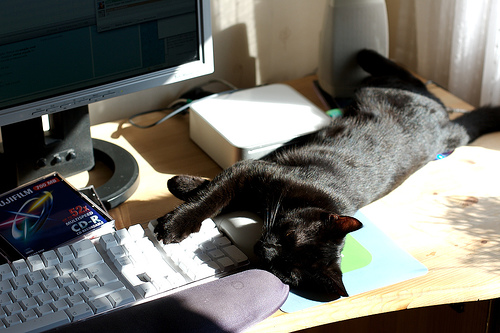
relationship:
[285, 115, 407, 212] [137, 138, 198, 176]
cat on table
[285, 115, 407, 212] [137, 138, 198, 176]
cat lying on table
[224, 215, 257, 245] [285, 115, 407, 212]
mouse under cat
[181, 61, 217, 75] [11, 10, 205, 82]
sunlight on monitor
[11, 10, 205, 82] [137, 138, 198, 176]
monitor on table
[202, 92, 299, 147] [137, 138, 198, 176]
router on table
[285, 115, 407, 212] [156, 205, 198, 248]
cat has foot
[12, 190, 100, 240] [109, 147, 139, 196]
case on base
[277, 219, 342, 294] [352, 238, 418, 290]
head on mouse pad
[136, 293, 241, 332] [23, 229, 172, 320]
wrist pad next to keyboard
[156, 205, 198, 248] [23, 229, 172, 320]
paw on keyboard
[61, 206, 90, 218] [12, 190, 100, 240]
print on case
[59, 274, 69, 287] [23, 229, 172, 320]
key on keyboard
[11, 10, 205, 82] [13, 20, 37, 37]
monitor with screen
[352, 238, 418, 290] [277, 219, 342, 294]
mouse pad under head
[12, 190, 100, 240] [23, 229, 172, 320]
case near keyboard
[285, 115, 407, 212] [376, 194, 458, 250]
cat lying in sunlight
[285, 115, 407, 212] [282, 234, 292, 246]
cat has eye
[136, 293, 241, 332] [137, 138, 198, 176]
wrist pad on table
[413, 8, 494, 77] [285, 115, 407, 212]
curtain behind cat